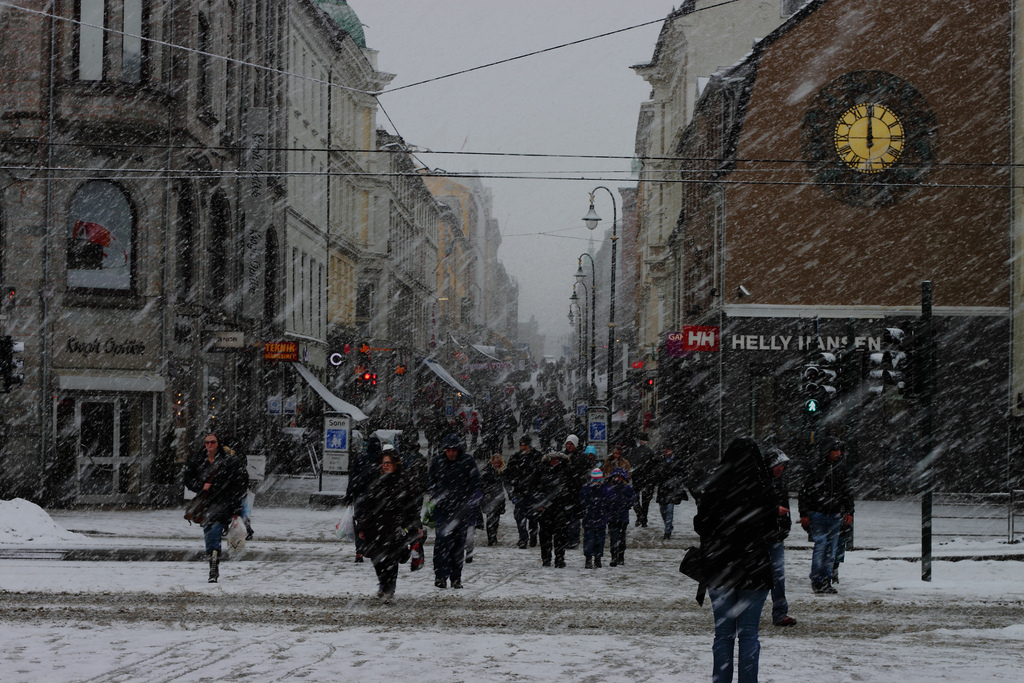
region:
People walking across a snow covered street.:
[378, 422, 666, 597]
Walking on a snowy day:
[17, 167, 351, 646]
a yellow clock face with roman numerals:
[822, 88, 915, 181]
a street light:
[578, 171, 636, 424]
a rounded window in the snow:
[47, 159, 156, 327]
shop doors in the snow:
[49, 357, 195, 523]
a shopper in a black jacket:
[170, 414, 263, 599]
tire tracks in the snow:
[0, 565, 696, 658]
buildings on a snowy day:
[3, 1, 541, 520]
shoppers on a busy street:
[340, 284, 629, 618]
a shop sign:
[724, 316, 892, 361]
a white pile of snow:
[0, 481, 118, 557]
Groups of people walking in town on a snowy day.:
[192, 360, 693, 604]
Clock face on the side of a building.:
[820, 89, 929, 211]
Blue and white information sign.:
[315, 395, 364, 516]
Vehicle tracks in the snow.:
[22, 576, 762, 647]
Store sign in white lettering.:
[681, 313, 898, 364]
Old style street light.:
[555, 178, 641, 448]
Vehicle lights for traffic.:
[351, 345, 410, 402]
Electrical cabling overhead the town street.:
[107, 33, 626, 230]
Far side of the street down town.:
[501, 320, 581, 404]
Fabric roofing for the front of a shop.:
[426, 357, 469, 397]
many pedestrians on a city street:
[239, 301, 922, 631]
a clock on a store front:
[737, 38, 1017, 253]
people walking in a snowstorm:
[110, 332, 961, 626]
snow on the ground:
[31, 494, 782, 671]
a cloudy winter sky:
[391, 35, 734, 440]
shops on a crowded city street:
[206, 157, 836, 521]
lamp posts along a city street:
[516, 162, 772, 532]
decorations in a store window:
[21, 149, 228, 479]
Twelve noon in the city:
[757, 37, 1021, 300]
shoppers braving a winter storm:
[261, 310, 939, 637]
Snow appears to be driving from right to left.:
[708, 68, 1021, 414]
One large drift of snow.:
[3, 480, 114, 592]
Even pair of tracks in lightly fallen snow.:
[81, 559, 879, 667]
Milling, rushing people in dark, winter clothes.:
[187, 349, 889, 647]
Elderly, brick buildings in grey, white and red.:
[85, 52, 1009, 489]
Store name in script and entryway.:
[44, 264, 203, 550]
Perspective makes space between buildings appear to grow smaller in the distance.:
[420, 69, 716, 563]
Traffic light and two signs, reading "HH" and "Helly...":
[677, 324, 1022, 527]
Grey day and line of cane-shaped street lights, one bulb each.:
[537, 195, 637, 540]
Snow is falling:
[230, 186, 840, 578]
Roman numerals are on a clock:
[792, 67, 938, 211]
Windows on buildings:
[205, 57, 394, 308]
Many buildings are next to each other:
[95, 24, 567, 398]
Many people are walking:
[312, 375, 883, 603]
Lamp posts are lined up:
[534, 172, 635, 487]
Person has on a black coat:
[686, 414, 783, 591]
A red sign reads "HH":
[665, 307, 748, 379]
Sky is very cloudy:
[456, 32, 592, 191]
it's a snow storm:
[81, 94, 922, 622]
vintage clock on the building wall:
[796, 82, 940, 256]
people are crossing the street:
[162, 414, 733, 591]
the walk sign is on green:
[786, 356, 864, 446]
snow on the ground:
[75, 613, 275, 675]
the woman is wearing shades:
[181, 432, 229, 455]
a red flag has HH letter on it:
[672, 313, 717, 371]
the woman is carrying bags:
[189, 480, 273, 556]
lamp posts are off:
[545, 158, 637, 446]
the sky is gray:
[399, 31, 587, 123]